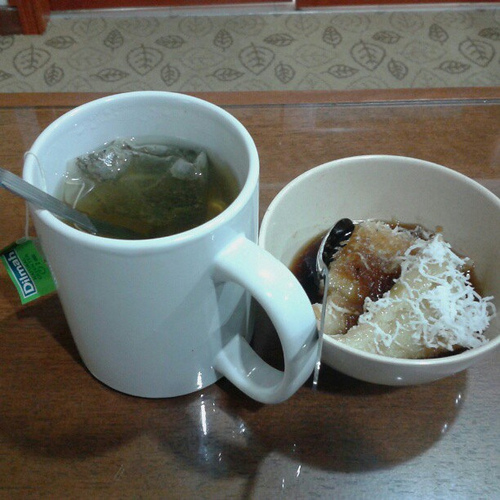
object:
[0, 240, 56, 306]
bag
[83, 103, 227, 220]
tea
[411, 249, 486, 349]
cheese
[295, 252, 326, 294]
coffee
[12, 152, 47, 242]
thread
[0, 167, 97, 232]
spoon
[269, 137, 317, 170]
ground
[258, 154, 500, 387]
bowl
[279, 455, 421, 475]
edge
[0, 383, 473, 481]
shadow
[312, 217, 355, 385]
teaspoon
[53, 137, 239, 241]
green tea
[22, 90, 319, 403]
cup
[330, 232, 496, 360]
coconut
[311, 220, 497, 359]
food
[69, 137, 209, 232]
tea bag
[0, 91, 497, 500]
table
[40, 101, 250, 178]
condensation